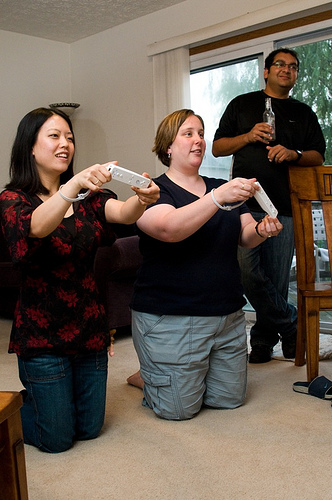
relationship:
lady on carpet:
[123, 107, 284, 422] [1, 316, 329, 498]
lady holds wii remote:
[123, 107, 284, 422] [253, 181, 277, 217]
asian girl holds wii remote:
[0, 106, 161, 454] [106, 163, 152, 188]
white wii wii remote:
[90, 189, 269, 221] [211, 181, 280, 220]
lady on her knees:
[157, 161, 242, 362] [116, 299, 272, 433]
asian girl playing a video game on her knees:
[0, 103, 161, 453] [26, 417, 107, 453]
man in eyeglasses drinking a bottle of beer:
[211, 47, 326, 365] [248, 89, 293, 129]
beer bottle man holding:
[260, 93, 281, 181] [235, 124, 297, 214]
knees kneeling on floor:
[27, 387, 252, 453] [0, 315, 331, 494]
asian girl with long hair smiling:
[0, 106, 161, 454] [13, 94, 115, 255]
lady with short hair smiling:
[123, 107, 284, 422] [165, 116, 211, 173]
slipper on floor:
[291, 372, 330, 400] [105, 392, 327, 498]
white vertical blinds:
[160, 69, 191, 93] [151, 55, 191, 108]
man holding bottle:
[211, 47, 326, 365] [260, 94, 277, 142]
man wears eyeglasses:
[211, 47, 326, 365] [264, 58, 299, 72]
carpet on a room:
[1, 316, 329, 498] [29, 424, 330, 500]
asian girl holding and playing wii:
[0, 106, 161, 454] [107, 160, 153, 193]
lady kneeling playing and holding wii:
[123, 107, 284, 422] [209, 178, 277, 217]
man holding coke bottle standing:
[203, 44, 330, 305] [256, 162, 303, 321]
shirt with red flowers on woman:
[9, 180, 153, 367] [41, 238, 114, 390]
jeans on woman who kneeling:
[27, 348, 135, 436] [49, 347, 111, 447]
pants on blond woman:
[158, 328, 248, 434] [166, 244, 245, 384]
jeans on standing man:
[239, 207, 297, 349] [259, 118, 309, 180]